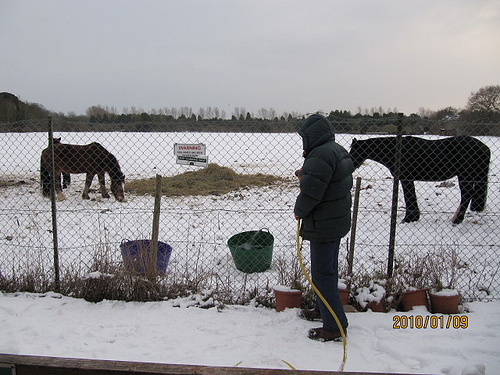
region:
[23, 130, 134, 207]
a horse in a field of snow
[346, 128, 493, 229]
a horse in a field of snow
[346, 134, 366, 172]
the head of a horse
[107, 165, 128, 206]
a horse in a field of snow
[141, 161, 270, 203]
a pile of hay in the snow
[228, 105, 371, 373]
a person filling a bucket with water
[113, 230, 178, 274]
a bucket in a field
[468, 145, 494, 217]
the tail of a horse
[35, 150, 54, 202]
the tail of a horse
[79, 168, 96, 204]
the front leg of a horse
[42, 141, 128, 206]
a brown horse grazing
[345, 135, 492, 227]
a black horse standing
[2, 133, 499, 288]
a snowy field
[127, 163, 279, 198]
a pile of brown hay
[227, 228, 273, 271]
a large green bucket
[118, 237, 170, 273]
a large blue bucket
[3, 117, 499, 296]
a long chicken wire fence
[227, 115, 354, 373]
a person spraying water into bucket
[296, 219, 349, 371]
a long yellow hose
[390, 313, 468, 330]
a yellow time stamp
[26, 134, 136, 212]
dark brown horse in the snow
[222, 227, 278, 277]
large green pail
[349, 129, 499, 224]
large black horse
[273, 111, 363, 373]
person with a hose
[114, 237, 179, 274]
large blue bucket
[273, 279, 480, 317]
small planting pots in the snow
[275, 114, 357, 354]
person in a black puffy jacket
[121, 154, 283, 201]
pile of hay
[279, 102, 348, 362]
person in blue pants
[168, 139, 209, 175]
white signs in the snow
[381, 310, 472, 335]
date stamp on the picture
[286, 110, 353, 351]
man standing outside the fence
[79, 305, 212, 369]
snow covers the ground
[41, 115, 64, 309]
fence post in the ground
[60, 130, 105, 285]
wire fence around the field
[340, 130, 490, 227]
horse in the field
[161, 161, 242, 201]
pile of hay in the field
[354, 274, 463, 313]
clay pots by the fence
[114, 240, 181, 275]
blue bucket on the ground